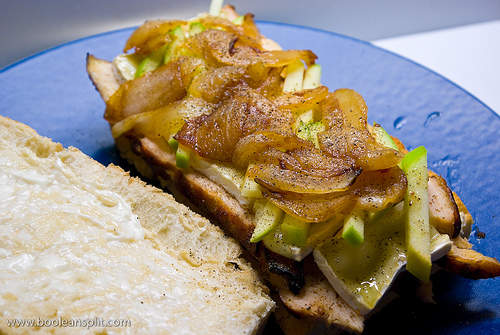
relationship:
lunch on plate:
[108, 68, 378, 267] [409, 70, 477, 141]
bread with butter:
[9, 130, 120, 325] [89, 184, 136, 216]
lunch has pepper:
[108, 68, 378, 267] [419, 182, 445, 205]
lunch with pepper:
[108, 68, 378, 267] [419, 182, 445, 205]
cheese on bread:
[346, 261, 351, 277] [9, 130, 120, 325]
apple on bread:
[416, 160, 432, 254] [9, 130, 120, 325]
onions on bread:
[206, 59, 239, 92] [9, 130, 120, 325]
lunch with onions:
[108, 68, 378, 267] [206, 59, 239, 92]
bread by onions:
[9, 130, 120, 325] [206, 59, 239, 92]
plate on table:
[409, 70, 477, 141] [460, 40, 489, 72]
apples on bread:
[342, 224, 378, 249] [9, 130, 120, 325]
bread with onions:
[9, 130, 120, 325] [206, 59, 239, 92]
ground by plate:
[347, 17, 376, 31] [409, 70, 477, 141]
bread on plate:
[9, 130, 120, 325] [409, 70, 477, 141]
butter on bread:
[89, 184, 136, 216] [9, 130, 120, 325]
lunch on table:
[108, 68, 378, 267] [460, 40, 489, 72]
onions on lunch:
[206, 59, 239, 92] [108, 68, 378, 267]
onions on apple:
[206, 59, 239, 92] [416, 160, 432, 254]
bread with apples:
[9, 130, 120, 325] [342, 224, 378, 249]